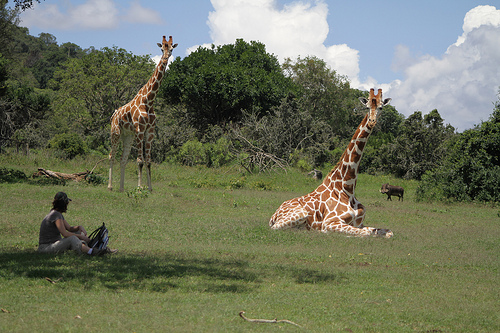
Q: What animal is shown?
A: Giraffe, boar.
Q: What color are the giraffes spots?
A: Brown.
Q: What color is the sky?
A: Blue.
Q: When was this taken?
A: Daytime.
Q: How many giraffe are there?
A: 2.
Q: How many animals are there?
A: 3.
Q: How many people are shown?
A: 1.